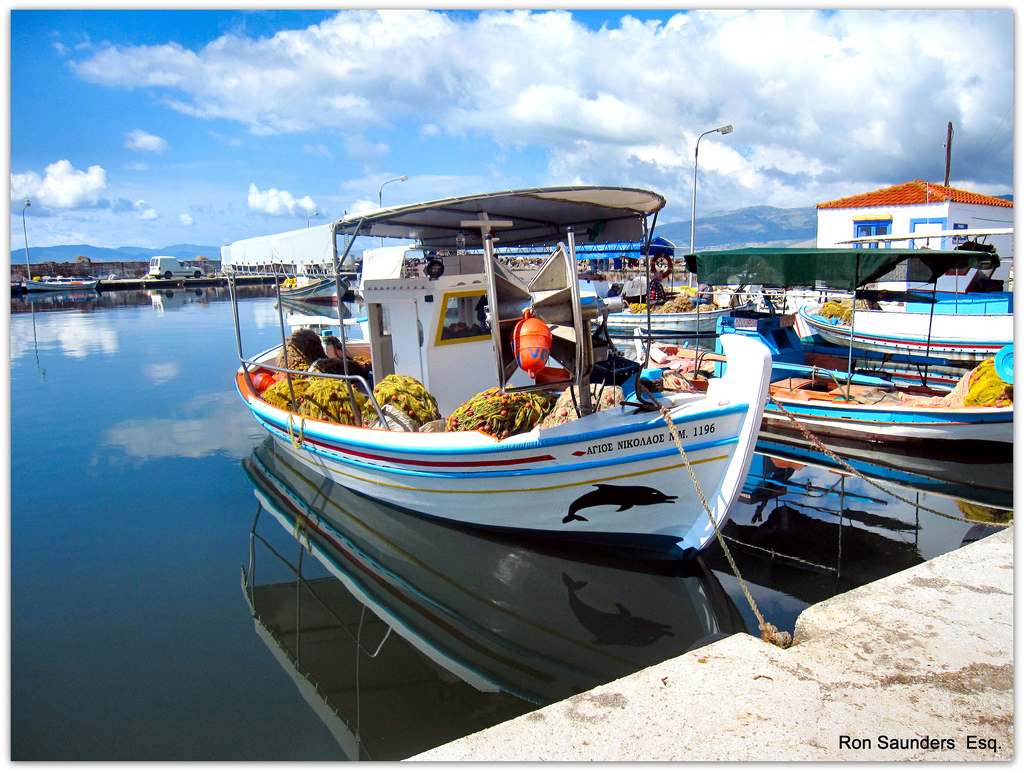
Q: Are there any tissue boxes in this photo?
A: No, there are no tissue boxes.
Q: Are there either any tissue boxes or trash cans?
A: No, there are no tissue boxes or trash cans.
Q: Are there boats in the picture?
A: Yes, there is a boat.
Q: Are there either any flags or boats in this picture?
A: Yes, there is a boat.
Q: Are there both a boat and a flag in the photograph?
A: No, there is a boat but no flags.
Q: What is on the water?
A: The boat is on the water.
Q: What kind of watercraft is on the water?
A: The watercraft is a boat.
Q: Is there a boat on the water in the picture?
A: Yes, there is a boat on the water.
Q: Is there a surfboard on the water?
A: No, there is a boat on the water.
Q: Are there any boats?
A: Yes, there is a boat.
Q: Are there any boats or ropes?
A: Yes, there is a boat.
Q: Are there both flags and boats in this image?
A: No, there is a boat but no flags.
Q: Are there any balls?
A: No, there are no balls.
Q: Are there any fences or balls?
A: No, there are no balls or fences.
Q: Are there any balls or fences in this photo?
A: No, there are no balls or fences.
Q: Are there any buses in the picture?
A: No, there are no buses.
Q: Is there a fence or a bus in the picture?
A: No, there are no buses or fences.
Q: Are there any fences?
A: No, there are no fences.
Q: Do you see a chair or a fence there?
A: No, there are no fences or chairs.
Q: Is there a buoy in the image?
A: Yes, there is a buoy.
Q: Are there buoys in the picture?
A: Yes, there is a buoy.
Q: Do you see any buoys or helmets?
A: Yes, there is a buoy.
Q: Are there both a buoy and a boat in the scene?
A: Yes, there are both a buoy and a boat.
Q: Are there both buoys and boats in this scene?
A: Yes, there are both a buoy and boats.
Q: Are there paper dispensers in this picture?
A: No, there are no paper dispensers.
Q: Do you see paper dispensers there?
A: No, there are no paper dispensers.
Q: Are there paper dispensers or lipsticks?
A: No, there are no paper dispensers or lipsticks.